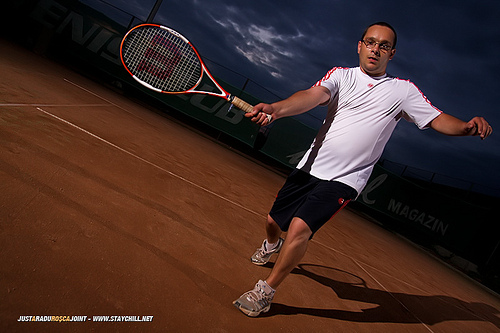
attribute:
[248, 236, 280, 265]
shoe — blue, white, sport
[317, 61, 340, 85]
stripe — red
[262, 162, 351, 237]
shorts — dark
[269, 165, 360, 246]
shorts — black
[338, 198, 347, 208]
parts — red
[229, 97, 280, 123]
handle — brown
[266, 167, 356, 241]
shorts — black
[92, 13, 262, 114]
racket — red, white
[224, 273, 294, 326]
shoe — white, grey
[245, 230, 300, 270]
shoe — grey, white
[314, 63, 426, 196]
shirt — red, white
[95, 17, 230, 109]
racket — white, red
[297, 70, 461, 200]
shirt — red, white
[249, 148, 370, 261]
shorts — red, black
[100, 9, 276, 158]
racket — red, white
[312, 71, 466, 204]
shirt — red, white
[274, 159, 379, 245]
shorts — red, black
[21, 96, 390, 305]
court — brown, white, lined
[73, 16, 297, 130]
sign — green, white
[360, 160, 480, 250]
sign — white, green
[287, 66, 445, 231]
shirt — red, white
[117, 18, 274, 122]
tennis racket — Wilson brand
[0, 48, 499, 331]
tennis court — brown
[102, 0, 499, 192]
sky — cloudy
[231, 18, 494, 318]
man — dressed for tennis, tennis player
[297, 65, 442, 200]
shirt — white, short sleeved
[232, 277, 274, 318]
shoe — tan, tennis shoe, white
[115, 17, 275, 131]
racket — white , red 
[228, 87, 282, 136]
tan handle — tan 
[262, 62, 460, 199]
white shirt — white 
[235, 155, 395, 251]
black shorts — black 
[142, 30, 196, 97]
red w — red 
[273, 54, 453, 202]
shirt — short sleeve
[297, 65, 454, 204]
shirt — white 